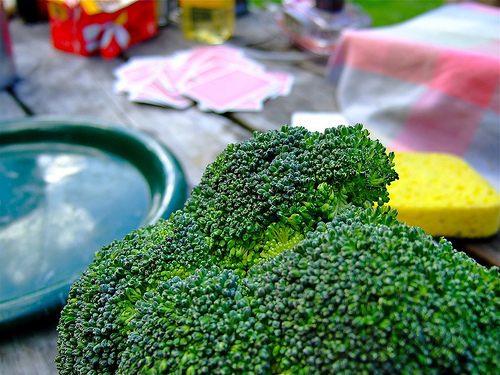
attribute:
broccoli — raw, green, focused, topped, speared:
[58, 127, 499, 374]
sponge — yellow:
[379, 145, 499, 241]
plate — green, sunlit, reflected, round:
[1, 114, 184, 330]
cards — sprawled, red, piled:
[111, 44, 296, 114]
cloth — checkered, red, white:
[328, 0, 496, 190]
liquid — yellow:
[180, 1, 240, 43]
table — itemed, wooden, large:
[3, 3, 498, 375]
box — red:
[44, 1, 161, 57]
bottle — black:
[282, 1, 371, 54]